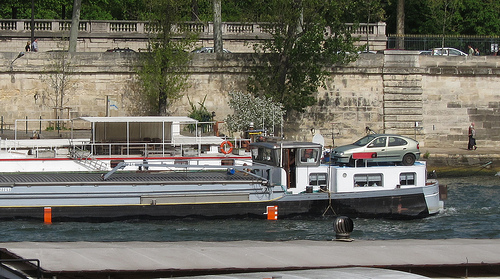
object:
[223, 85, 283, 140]
tree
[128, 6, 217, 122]
tree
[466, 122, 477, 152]
person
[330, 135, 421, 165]
car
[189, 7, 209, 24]
branch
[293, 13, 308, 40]
branch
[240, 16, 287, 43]
branch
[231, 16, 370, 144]
tree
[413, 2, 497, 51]
tree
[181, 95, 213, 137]
tree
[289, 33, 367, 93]
branch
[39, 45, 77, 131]
tree